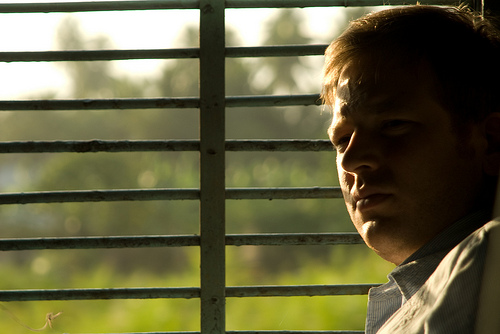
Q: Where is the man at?
A: Inside building.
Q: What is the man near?
A: Blinds.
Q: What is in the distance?
A: Trees.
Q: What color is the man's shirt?
A: White.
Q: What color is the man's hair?
A: Brown.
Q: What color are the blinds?
A: Black.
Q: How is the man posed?
A: Leaning.